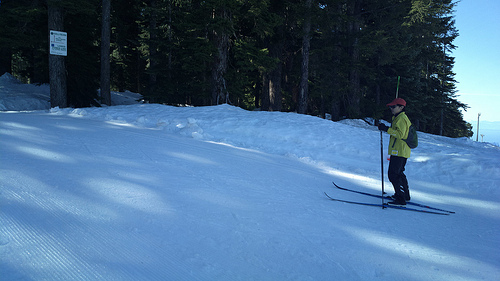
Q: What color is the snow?
A: White.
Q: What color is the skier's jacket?
A: Yellow.